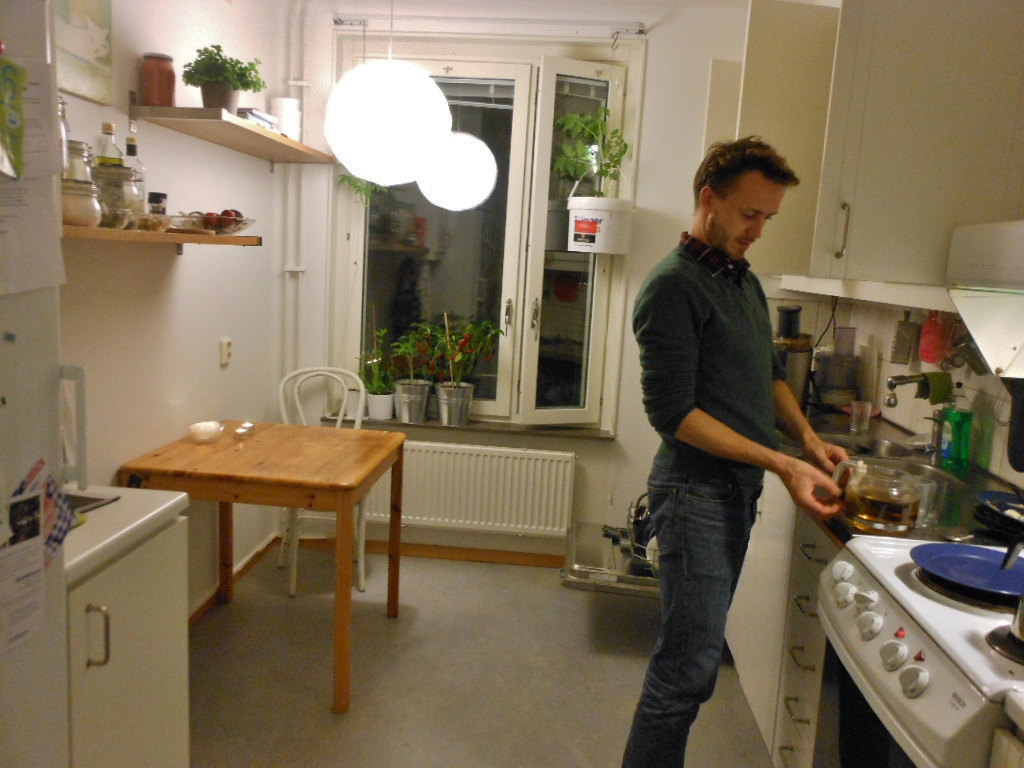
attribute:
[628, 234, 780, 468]
shirt — green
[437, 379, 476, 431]
tin — metal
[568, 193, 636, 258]
pail — white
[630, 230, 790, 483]
shirt — black, short sleeved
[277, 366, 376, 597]
chair — white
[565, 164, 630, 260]
pail — white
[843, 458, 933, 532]
pitcher — glass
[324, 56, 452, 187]
light — spherical, white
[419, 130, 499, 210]
light — spherical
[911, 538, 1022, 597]
plate — blue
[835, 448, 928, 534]
pitcher — glass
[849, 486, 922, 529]
liquid — amber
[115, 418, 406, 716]
table — small, wooden, dining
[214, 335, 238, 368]
outlet — electrical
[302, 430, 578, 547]
radiator — white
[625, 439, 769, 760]
jeans — blue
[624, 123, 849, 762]
man — slender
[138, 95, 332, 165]
shelf — highest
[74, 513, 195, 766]
cupboard — closed